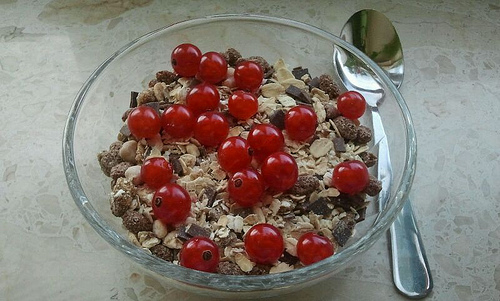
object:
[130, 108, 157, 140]
cherry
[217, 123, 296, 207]
red berries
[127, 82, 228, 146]
red berries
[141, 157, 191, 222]
red berries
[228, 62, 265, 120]
red berries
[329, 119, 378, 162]
cereal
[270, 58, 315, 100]
cereal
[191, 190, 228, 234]
cereal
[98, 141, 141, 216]
cereal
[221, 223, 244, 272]
cereal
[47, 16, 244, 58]
shadow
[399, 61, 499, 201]
counter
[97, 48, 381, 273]
oatmeal flakes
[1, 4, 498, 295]
white counter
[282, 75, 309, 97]
chocolate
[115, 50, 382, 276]
nuts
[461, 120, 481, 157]
ground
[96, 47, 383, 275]
granola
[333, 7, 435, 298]
spoon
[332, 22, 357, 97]
reflection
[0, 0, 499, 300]
surface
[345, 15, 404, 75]
reflection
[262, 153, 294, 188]
cherries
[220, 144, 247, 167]
cherries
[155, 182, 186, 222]
cherries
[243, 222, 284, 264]
cherry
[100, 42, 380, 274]
cereal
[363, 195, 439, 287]
silver spoon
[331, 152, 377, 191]
cherry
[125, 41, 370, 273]
cherries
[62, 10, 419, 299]
bowl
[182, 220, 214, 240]
chocolate chip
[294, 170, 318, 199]
chocolate chip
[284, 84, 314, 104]
chocolate chip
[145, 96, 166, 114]
chocolate chip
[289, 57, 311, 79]
chocolate chip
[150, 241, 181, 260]
raisins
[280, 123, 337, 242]
cereal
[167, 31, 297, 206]
cherries